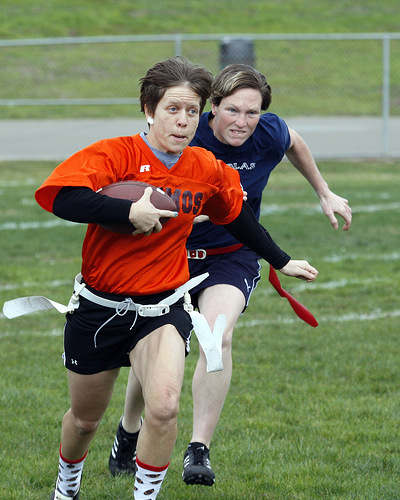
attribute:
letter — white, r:
[141, 161, 155, 175]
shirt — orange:
[38, 134, 242, 295]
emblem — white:
[70, 356, 80, 369]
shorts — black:
[59, 278, 197, 375]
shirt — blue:
[174, 109, 293, 256]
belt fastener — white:
[185, 251, 209, 260]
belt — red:
[187, 236, 321, 339]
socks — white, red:
[53, 449, 174, 496]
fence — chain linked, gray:
[3, 30, 400, 159]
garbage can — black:
[214, 38, 261, 74]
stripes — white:
[106, 441, 217, 471]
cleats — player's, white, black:
[109, 417, 225, 488]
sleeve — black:
[52, 182, 133, 229]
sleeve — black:
[226, 204, 292, 275]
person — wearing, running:
[35, 56, 332, 495]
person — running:
[101, 58, 359, 487]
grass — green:
[0, 8, 395, 496]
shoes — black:
[110, 422, 218, 484]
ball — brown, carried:
[92, 182, 177, 228]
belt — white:
[69, 268, 215, 323]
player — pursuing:
[102, 62, 358, 487]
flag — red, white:
[190, 308, 232, 386]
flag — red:
[264, 261, 325, 334]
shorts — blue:
[174, 243, 262, 309]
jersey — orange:
[24, 136, 248, 296]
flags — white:
[1, 290, 232, 371]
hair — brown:
[139, 56, 218, 115]